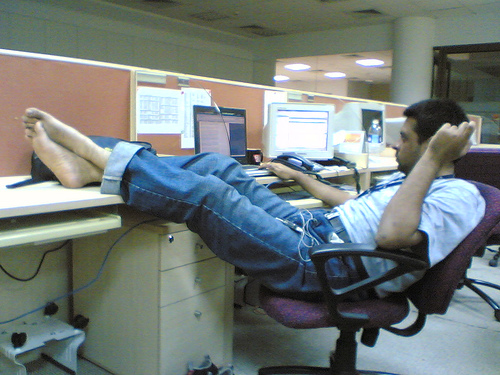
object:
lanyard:
[363, 178, 411, 193]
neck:
[434, 162, 456, 178]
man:
[21, 98, 487, 297]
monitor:
[192, 104, 247, 161]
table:
[1, 171, 82, 217]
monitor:
[264, 102, 333, 163]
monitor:
[340, 104, 387, 153]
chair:
[251, 176, 494, 374]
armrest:
[308, 243, 424, 325]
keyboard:
[240, 164, 272, 175]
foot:
[22, 107, 113, 186]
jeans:
[100, 133, 341, 296]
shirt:
[332, 169, 485, 296]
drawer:
[160, 228, 219, 274]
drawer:
[160, 255, 222, 308]